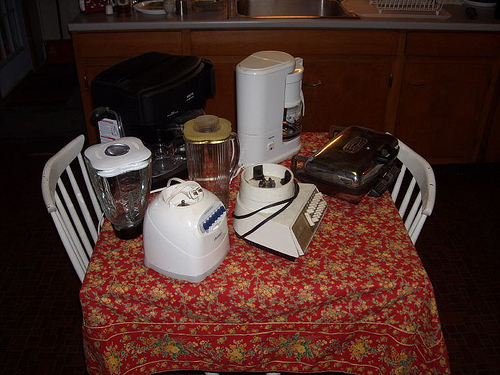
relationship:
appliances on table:
[86, 50, 404, 284] [89, 127, 430, 320]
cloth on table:
[108, 134, 417, 309] [86, 121, 430, 352]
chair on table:
[39, 126, 435, 231] [74, 119, 447, 369]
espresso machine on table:
[91, 44, 214, 183] [79, 96, 454, 368]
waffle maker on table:
[292, 118, 401, 199] [74, 119, 447, 369]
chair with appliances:
[39, 126, 435, 231] [83, 136, 153, 240]